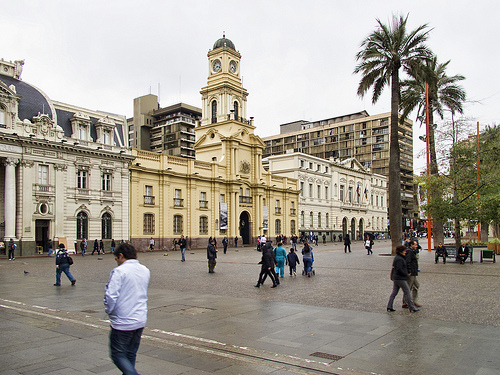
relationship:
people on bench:
[437, 241, 470, 265] [436, 244, 474, 263]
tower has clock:
[195, 31, 265, 173] [211, 56, 238, 75]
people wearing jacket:
[251, 237, 316, 292] [260, 250, 274, 271]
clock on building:
[211, 56, 238, 75] [128, 31, 302, 253]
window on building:
[173, 189, 184, 235] [128, 31, 302, 253]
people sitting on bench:
[437, 241, 470, 265] [434, 240, 472, 262]